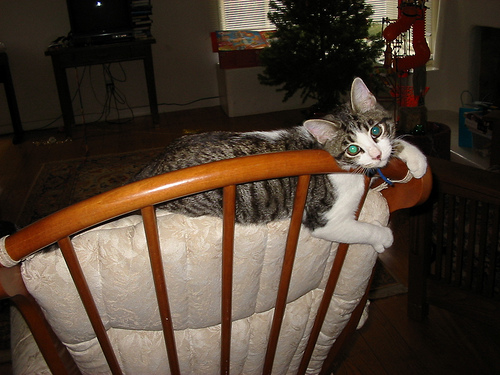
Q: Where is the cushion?
A: On the chair.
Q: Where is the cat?
A: On the chair.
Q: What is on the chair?
A: A white pad.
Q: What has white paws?
A: The cat.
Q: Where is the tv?
A: Near the window.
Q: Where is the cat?
A: In a chair.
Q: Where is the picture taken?
A: A living room.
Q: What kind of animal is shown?
A: A cat.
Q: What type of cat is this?
A: Tabby.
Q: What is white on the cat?
A: It's chest.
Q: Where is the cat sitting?
A: A chair.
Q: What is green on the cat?
A: Eyes.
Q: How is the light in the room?
A: Low.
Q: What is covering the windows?
A: Blinds.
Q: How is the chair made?
A: Of wood.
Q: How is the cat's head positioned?
A: It is cocked.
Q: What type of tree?
A: Christmas.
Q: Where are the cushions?
A: On chair.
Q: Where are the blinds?
A: On window.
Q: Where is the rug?
A: On carpet.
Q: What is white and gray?
A: Cat.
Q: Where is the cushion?
A: On chair.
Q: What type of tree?
A: Pine.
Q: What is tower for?
A: Cat.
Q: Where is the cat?
A: On chair.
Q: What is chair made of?
A: Wood.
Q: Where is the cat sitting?
A: In a chair.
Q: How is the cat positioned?
A: With it's head on the rail.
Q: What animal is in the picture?
A: A cat.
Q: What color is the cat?
A: White and grey.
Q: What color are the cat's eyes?
A: Green.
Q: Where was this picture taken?
A: A living room.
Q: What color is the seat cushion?
A: Cream.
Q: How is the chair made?
A: Of wood.